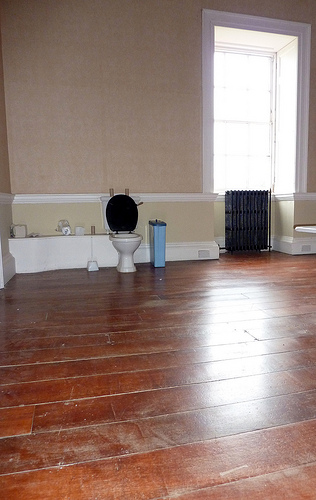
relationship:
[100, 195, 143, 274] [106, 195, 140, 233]
toilet has seat cover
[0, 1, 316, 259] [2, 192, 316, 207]
wall has molding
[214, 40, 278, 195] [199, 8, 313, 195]
window has frame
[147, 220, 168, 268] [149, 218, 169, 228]
trash can has lid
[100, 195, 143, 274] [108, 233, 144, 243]
toilet has seat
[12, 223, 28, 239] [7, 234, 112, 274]
item on shelf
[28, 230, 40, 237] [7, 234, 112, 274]
item on shelf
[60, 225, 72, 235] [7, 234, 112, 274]
item on shelf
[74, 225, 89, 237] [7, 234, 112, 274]
item on shelf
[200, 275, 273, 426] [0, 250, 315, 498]
reflection on floor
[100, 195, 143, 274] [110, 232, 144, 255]
toilet has bowl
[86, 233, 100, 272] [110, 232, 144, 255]
toilet cleaner near bowl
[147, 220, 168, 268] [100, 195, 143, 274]
trash can near toilet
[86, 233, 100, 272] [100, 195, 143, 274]
toilet cleaner near toilet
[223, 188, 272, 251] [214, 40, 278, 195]
radiator near window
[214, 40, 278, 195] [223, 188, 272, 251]
window above radiator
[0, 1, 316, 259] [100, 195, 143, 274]
wall above toilet